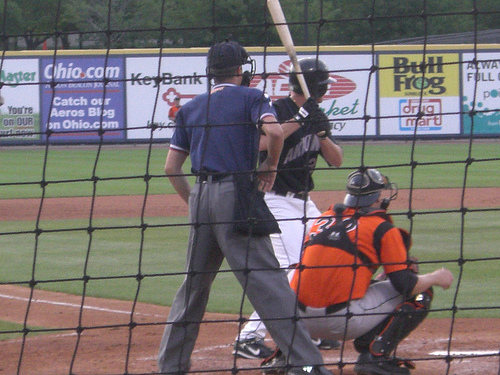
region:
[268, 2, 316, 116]
The bat is wood.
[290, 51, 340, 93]
He is wearing a helmet.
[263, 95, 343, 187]
His jersey is black.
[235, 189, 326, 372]
He is wearing white pants.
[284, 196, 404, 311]
He is wearing an orange jersey.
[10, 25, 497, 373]
They are playing baseball.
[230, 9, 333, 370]
He is batting.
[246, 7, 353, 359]
He is swinging the bat.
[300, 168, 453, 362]
He is the catcher.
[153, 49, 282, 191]
He is wearing a blue shirt.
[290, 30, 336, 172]
man holding a bat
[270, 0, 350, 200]
man wearing a helmet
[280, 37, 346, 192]
man wearing a t shirt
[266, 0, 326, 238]
man wearing white pants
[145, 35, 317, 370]
man wearing a hat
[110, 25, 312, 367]
man wearing a shirt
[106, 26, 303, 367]
man wearing gray pants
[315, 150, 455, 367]
man squatting next to a man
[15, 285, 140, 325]
white line on field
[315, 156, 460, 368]
man wearing gray pants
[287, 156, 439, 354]
CATCHER IS WEARING NUMBER 32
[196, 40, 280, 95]
UMPIRE IS WEARING A MASK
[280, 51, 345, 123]
BATTER IS WEARING A HELMET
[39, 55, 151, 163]
OHIO.COM IS A SPONSOR ON THE WALL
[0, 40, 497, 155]
MANY POSTERS LINE THE BACK WALL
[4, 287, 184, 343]
WHITE LINES ARE ON THE BASEBALL FIELD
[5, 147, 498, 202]
GREEN GRASS IS IN THE OUTFIELD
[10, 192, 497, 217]
DIRT RINGS AROUND THE BALL FIELD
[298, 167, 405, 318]
CATCHER IS WEARING AN ORANGE SHIRT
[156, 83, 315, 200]
UMPIRE IS WEARING A BLUE SHIRT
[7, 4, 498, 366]
black string of net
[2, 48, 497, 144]
advertisments on back wall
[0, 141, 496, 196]
green grass of field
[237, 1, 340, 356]
player standing with bat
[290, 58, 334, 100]
black helmet on head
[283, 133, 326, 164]
word on front of shirt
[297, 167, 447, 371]
back of squatting catcher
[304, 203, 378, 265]
black straps on back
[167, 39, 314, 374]
umpire with spread legs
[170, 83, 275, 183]
blue shirt with white trim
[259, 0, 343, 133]
Player holding a baseball bat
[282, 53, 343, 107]
Player wearing a black batting helmet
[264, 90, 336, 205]
Player wearing black jersey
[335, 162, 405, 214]
Player wearing a catchers mask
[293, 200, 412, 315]
Player wearing an orange jersey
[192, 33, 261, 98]
A baseball umpire wearing a mask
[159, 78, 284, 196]
An umpire wearing a blue shirt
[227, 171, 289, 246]
A black bag containing baseballs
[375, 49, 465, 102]
A yellow Bull Frog advertising sign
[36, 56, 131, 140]
A blue and white advertising sign for Ohio.com